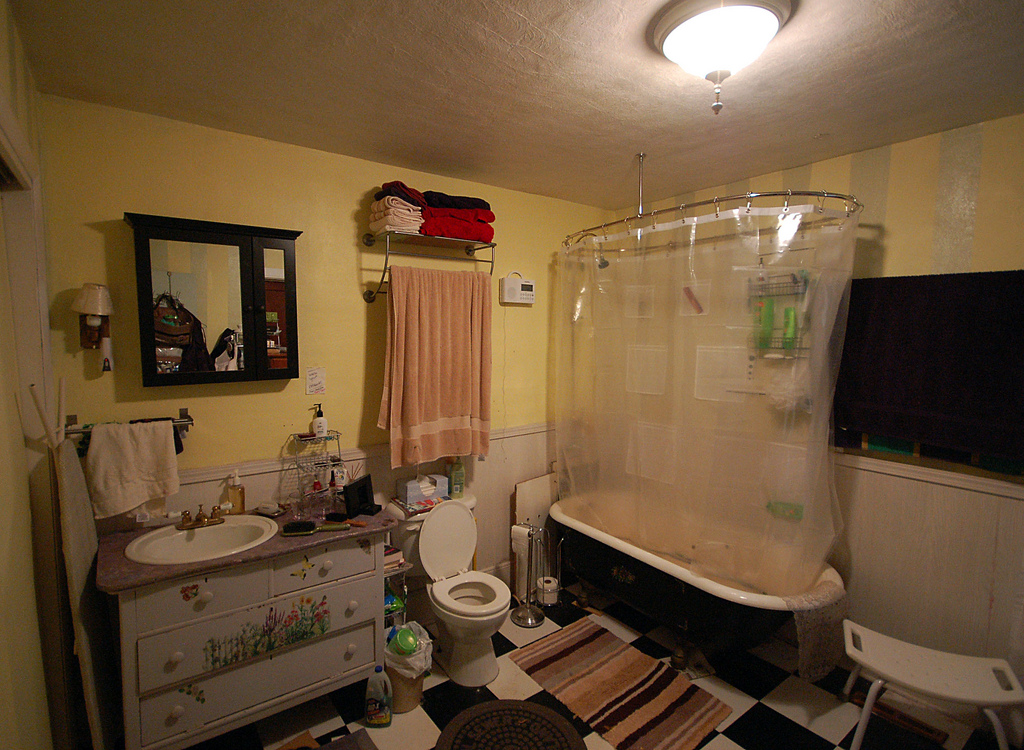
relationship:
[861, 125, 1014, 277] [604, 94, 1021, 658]
tile in wall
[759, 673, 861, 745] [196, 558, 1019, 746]
tile on floor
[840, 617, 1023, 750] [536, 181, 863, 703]
stool next to shower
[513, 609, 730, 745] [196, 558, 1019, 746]
rug on floor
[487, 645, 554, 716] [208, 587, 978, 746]
tile on floor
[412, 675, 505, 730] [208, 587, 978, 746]
tile on floor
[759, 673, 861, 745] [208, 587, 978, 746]
tile on floor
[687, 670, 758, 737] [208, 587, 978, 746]
tile on floor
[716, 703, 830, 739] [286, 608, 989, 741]
tile on floor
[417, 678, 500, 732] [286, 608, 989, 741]
tile on floor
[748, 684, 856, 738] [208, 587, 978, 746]
tile on floor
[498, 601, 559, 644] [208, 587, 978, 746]
tile on floor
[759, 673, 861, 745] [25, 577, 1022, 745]
tile on floor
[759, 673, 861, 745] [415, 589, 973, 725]
tile on floor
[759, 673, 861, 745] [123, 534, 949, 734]
tile on floor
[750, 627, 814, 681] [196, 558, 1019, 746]
tile on floor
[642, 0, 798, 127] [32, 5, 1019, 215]
light on ceiling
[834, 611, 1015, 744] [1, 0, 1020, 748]
stool in bathroom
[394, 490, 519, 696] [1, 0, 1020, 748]
toilet in bathroom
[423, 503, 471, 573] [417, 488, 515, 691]
lid on toilet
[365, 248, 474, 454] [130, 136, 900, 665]
towel in bathroom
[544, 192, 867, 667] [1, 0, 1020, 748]
shower in bathroom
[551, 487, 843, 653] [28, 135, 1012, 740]
bathtub in bathroom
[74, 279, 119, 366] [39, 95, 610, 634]
light on wall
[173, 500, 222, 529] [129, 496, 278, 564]
faucet on sink